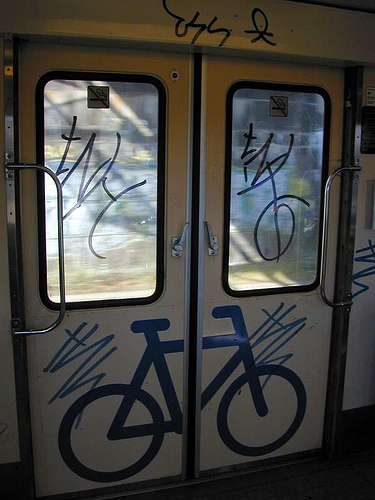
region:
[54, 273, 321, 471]
a blue bike clipart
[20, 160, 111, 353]
a silver metal handle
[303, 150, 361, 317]
a silver metal handle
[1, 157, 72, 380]
a silver metal handle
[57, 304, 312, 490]
The symbol on the door is a bicycle.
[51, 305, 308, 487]
There is a blue bicycle on the door.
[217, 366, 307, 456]
The front wheel is round.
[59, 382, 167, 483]
The back wheel is round.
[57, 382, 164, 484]
The back wheel is blue.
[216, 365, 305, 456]
The front wheel is blue.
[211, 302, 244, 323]
The handle bar is blue.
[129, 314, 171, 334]
The bicycle seat is blue.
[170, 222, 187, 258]
The door knob is silver.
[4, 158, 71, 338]
The door handle bar is silver.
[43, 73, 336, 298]
two windows on train door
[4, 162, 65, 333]
silver metal handles on train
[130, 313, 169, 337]
black bike seat on image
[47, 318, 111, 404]
blue graffiti on door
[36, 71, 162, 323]
window on door of train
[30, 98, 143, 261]
black graffiti on train door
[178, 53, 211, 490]
black and silver middle of doors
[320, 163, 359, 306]
silver handle on door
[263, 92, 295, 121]
no smoking sign on train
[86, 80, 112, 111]
no smoking sign on train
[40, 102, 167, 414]
doodles on the door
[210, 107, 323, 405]
doodles on the door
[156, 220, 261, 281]
door handles are silver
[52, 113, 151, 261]
dark colore graffitti on a window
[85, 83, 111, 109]
no smoking labe on a window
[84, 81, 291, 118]
two non smoking stickers on a window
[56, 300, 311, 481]
blue bicycle graphic on a door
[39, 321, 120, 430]
blue graffitti on a door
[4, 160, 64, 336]
silver handle on a train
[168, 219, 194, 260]
silver handle on a white door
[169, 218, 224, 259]
two silver handles on white doors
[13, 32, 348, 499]
white double doors with a blue bicycle graphic on it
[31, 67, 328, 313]
double windows with no smoking stickers on it